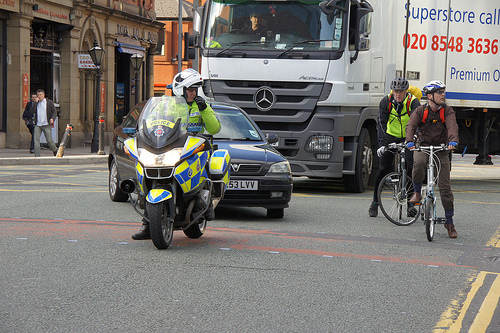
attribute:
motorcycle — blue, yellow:
[120, 98, 231, 248]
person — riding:
[404, 80, 461, 244]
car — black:
[111, 97, 293, 222]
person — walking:
[32, 90, 59, 158]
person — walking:
[21, 96, 45, 154]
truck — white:
[176, 1, 496, 190]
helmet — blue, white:
[424, 80, 449, 90]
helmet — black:
[392, 77, 409, 89]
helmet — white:
[170, 69, 204, 95]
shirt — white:
[33, 100, 56, 130]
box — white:
[391, 0, 499, 120]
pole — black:
[89, 41, 110, 153]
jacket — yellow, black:
[376, 96, 420, 150]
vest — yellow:
[388, 93, 416, 141]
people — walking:
[23, 89, 62, 159]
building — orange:
[151, 1, 231, 102]